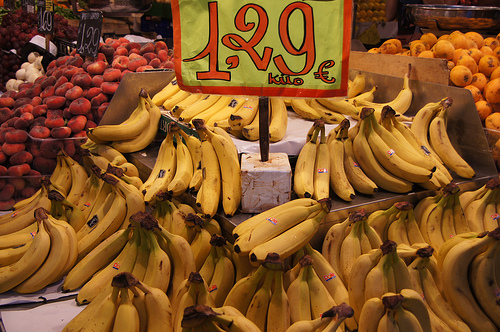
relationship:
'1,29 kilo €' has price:
[180, 0, 336, 86] [183, 1, 338, 83]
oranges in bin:
[364, 28, 499, 153] [349, 47, 498, 147]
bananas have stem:
[0, 66, 500, 332] [309, 117, 327, 131]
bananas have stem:
[0, 66, 500, 332] [189, 117, 205, 133]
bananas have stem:
[229, 193, 335, 272] [318, 196, 334, 216]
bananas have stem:
[0, 66, 500, 332] [165, 119, 182, 133]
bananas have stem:
[81, 84, 164, 157] [137, 86, 149, 98]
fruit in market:
[0, 0, 499, 332] [2, 1, 499, 331]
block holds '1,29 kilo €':
[238, 149, 293, 216] [180, 0, 336, 86]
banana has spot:
[143, 226, 170, 299] [158, 258, 165, 274]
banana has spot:
[230, 198, 325, 257] [233, 237, 242, 244]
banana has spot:
[416, 192, 452, 259] [432, 210, 438, 223]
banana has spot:
[429, 116, 475, 183] [436, 119, 445, 150]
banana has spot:
[308, 94, 346, 125] [322, 110, 332, 118]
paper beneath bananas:
[155, 94, 430, 159] [148, 60, 415, 142]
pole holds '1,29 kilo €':
[255, 97, 276, 166] [180, 0, 336, 86]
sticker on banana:
[315, 166, 326, 176] [315, 122, 332, 211]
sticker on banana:
[322, 270, 337, 286] [304, 244, 349, 307]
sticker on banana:
[156, 167, 170, 182] [142, 122, 178, 205]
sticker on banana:
[420, 144, 431, 155] [390, 115, 453, 182]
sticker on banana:
[84, 214, 100, 230] [78, 188, 118, 242]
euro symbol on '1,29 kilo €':
[310, 53, 338, 87] [180, 0, 336, 86]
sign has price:
[78, 9, 104, 59] [76, 23, 100, 57]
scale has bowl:
[401, 2, 500, 49] [402, 4, 499, 27]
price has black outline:
[183, 1, 338, 83] [183, 0, 338, 88]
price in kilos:
[183, 1, 338, 83] [266, 71, 306, 90]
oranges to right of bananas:
[364, 28, 499, 153] [0, 60, 499, 330]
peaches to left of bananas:
[0, 32, 174, 214] [0, 60, 499, 330]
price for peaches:
[76, 23, 100, 57] [0, 32, 174, 214]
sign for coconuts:
[35, 9, 55, 37] [0, 51, 46, 101]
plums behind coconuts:
[0, 46, 26, 95] [0, 51, 46, 101]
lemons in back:
[355, 1, 386, 24] [1, 2, 499, 38]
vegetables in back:
[3, 1, 84, 20] [1, 2, 499, 38]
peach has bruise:
[125, 49, 149, 70] [129, 57, 142, 63]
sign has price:
[357, 22, 382, 48] [364, 28, 379, 42]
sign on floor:
[357, 22, 382, 48] [362, 37, 403, 53]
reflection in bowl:
[408, 14, 496, 30] [402, 4, 499, 27]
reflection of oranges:
[408, 14, 496, 30] [364, 28, 499, 153]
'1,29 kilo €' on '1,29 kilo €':
[184, 0, 339, 95] [180, 0, 336, 86]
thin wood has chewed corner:
[349, 51, 450, 84] [437, 57, 452, 71]